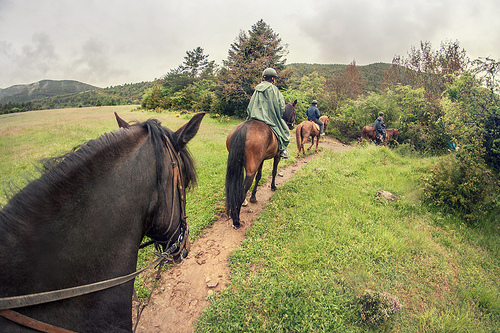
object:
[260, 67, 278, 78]
helmets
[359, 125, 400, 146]
horse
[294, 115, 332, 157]
horse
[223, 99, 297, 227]
horse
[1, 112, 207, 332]
horse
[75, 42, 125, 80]
clouds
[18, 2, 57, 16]
sky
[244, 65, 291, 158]
person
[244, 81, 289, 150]
jacket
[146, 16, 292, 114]
trees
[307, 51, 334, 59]
clouds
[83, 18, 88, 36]
sky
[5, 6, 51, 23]
sky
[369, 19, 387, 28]
clouds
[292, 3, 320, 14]
sky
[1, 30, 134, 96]
cloud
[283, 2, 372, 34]
cloud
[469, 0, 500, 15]
sky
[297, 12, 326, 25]
clouds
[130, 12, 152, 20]
sky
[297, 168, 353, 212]
ground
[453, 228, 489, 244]
grass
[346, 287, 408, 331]
pink flowers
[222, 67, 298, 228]
people